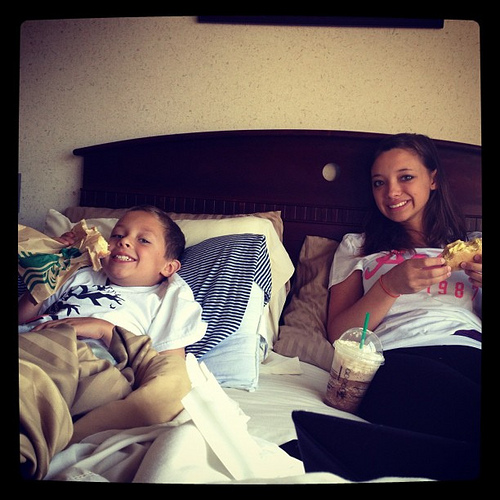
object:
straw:
[359, 312, 369, 349]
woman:
[326, 133, 482, 444]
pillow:
[176, 233, 274, 393]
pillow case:
[176, 233, 274, 359]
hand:
[387, 256, 451, 294]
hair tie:
[379, 275, 400, 298]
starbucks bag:
[17, 218, 112, 304]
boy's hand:
[53, 232, 75, 246]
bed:
[19, 129, 498, 484]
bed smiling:
[57, 116, 399, 222]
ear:
[160, 259, 181, 277]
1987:
[427, 280, 479, 300]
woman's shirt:
[328, 231, 482, 351]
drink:
[323, 312, 385, 413]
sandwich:
[441, 238, 483, 271]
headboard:
[72, 128, 480, 326]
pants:
[356, 345, 484, 443]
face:
[102, 210, 160, 278]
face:
[372, 148, 430, 223]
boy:
[20, 208, 209, 364]